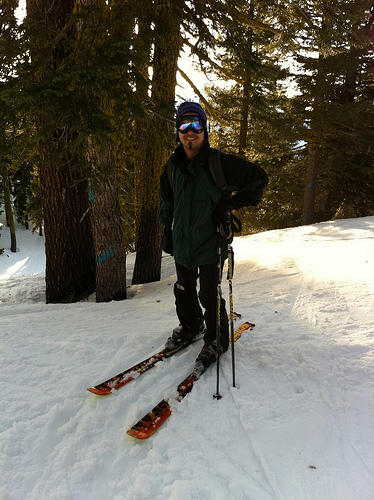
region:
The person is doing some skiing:
[46, 79, 330, 473]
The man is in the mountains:
[48, 82, 332, 481]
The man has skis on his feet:
[71, 57, 331, 474]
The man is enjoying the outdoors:
[68, 63, 309, 496]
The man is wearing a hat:
[72, 46, 326, 450]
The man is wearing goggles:
[55, 59, 321, 484]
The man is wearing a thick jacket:
[71, 61, 316, 484]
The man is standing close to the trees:
[45, 58, 317, 481]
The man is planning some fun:
[51, 48, 341, 461]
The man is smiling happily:
[52, 51, 344, 482]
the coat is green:
[178, 199, 197, 228]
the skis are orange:
[133, 412, 177, 434]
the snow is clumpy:
[36, 362, 77, 433]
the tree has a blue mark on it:
[90, 243, 116, 264]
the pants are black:
[186, 284, 196, 313]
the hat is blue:
[171, 95, 213, 128]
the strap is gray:
[206, 148, 230, 188]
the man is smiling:
[178, 134, 206, 145]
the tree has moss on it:
[157, 50, 170, 106]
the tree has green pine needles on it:
[51, 69, 88, 102]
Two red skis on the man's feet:
[123, 319, 261, 449]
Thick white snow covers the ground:
[260, 271, 368, 483]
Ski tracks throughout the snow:
[187, 398, 278, 483]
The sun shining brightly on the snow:
[249, 225, 368, 290]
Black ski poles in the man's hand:
[191, 187, 255, 399]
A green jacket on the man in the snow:
[156, 148, 239, 276]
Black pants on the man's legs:
[162, 251, 252, 362]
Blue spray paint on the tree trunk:
[97, 247, 122, 273]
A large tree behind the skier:
[27, 5, 100, 288]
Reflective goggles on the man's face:
[177, 115, 202, 133]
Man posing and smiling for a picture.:
[154, 99, 270, 395]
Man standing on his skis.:
[86, 99, 270, 446]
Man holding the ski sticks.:
[206, 189, 244, 401]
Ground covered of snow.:
[258, 238, 366, 491]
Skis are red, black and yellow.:
[79, 306, 254, 436]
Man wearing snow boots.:
[162, 280, 236, 368]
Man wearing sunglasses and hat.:
[170, 99, 208, 132]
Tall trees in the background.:
[1, 6, 164, 309]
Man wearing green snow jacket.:
[155, 144, 258, 272]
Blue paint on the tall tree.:
[92, 241, 127, 266]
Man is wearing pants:
[162, 252, 231, 354]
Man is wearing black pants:
[169, 254, 233, 353]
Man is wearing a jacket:
[157, 141, 268, 268]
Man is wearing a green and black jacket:
[152, 140, 267, 267]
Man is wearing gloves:
[157, 193, 242, 255]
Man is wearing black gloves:
[156, 196, 242, 255]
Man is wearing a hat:
[173, 97, 209, 123]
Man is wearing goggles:
[173, 116, 209, 133]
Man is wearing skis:
[86, 305, 256, 439]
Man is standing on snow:
[88, 99, 257, 442]